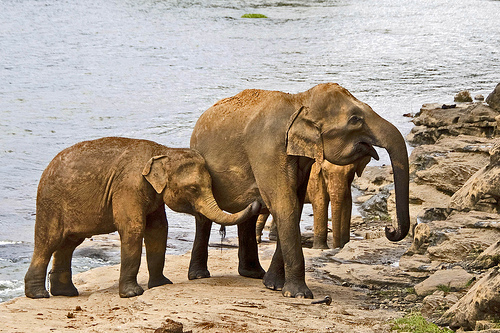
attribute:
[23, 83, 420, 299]
elephants — brown, grey, walking, small, standing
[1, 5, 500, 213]
water — shallow, blue, white, calm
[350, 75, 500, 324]
rocks — big, grey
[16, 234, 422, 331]
sand — white, tan, brown